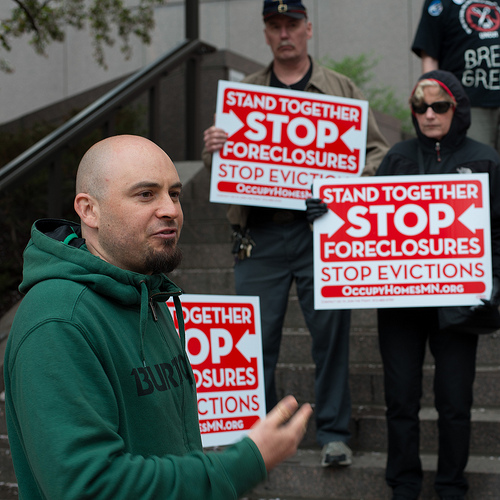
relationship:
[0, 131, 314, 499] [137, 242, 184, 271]
male has goatee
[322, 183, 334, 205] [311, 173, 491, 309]
letter on sign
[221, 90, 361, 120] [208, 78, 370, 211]
white lettering printed on red sign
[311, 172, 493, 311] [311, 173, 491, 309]
sign printed on sign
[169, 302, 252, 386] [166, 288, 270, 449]
white lettering printed on sign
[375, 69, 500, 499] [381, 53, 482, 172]
person wearing hood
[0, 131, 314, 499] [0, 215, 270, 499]
male wears hoodie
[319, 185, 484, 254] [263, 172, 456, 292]
lettering on sign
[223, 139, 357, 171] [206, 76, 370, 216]
lettering on sign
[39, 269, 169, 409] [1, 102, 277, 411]
sweater on man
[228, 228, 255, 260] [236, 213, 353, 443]
keys are hanging off pants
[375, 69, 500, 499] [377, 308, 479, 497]
person wearing black pants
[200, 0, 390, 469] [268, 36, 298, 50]
man has a moustache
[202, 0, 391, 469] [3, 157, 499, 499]
man standing on stairs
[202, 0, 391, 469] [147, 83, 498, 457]
man are holding signs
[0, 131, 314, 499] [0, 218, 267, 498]
male wearing a hoodie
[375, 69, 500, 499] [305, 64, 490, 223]
person wearing a jacket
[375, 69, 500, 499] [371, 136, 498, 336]
person wearing a jacket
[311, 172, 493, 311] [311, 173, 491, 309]
sign on sign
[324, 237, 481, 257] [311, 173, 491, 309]
lettering on sign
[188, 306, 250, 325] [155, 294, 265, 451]
lettering on sign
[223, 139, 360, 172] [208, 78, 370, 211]
lettering on red sign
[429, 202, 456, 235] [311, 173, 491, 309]
letter on sign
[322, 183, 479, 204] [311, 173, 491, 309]
lettering on sign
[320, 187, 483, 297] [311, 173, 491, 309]
lettering on sign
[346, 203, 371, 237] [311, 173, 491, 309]
letter on sign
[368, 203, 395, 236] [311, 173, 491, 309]
letter on sign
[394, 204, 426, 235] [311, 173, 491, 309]
letter on sign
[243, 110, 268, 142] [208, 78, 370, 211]
letter on red sign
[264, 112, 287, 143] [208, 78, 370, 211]
letter on red sign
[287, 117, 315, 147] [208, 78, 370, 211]
letter on red sign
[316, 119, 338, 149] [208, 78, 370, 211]
letter on red sign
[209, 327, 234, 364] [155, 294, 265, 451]
letter on sign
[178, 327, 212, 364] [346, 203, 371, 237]
letter on letter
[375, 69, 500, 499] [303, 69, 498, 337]
person in a hood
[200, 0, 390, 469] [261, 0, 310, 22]
man wearing hat